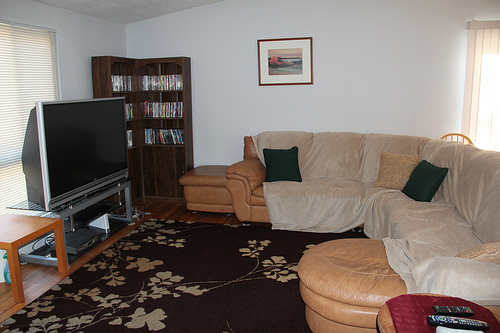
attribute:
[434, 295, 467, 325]
remote — black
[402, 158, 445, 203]
pillow — green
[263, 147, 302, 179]
pillow — green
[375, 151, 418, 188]
pillow — green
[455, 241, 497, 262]
pillow — green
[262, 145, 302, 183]
pillow — green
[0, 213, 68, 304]
table — brown, wooden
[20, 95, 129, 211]
television — large, silver, grey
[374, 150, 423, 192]
pillow — small, brown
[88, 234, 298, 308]
carpet — brown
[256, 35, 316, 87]
picture — brown, framed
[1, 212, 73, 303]
side table — wooden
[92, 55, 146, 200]
bookcase — wooden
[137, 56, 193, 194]
bookcase — wooden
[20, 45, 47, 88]
blinds — white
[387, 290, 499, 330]
cloth — red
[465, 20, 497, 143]
curtain — sheer, white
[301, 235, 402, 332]
ottoman — brown, large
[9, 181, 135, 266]
stand — grey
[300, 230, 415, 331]
ottoman — tan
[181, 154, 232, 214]
ottoman — tan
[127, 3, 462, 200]
wall — white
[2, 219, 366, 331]
rug — brown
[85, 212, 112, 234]
console — white